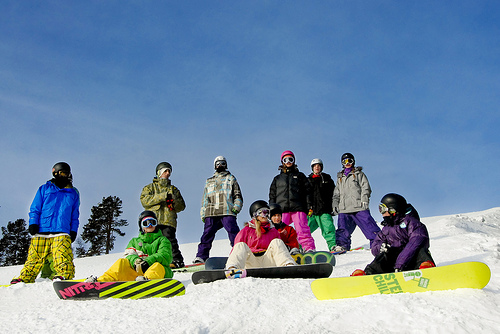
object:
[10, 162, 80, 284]
man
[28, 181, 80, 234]
blue jacket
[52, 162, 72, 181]
black mask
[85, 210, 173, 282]
man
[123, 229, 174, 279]
green jacket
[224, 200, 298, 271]
girl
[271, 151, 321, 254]
woman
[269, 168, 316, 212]
black jacket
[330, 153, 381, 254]
female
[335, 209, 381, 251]
purple pants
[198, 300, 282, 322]
snow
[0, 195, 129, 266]
trees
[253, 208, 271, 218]
goggled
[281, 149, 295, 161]
helmet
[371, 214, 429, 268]
jacket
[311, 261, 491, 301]
snowboard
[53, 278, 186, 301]
snowboard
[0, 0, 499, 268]
sky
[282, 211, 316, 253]
pants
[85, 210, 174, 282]
person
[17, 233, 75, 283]
yellow pants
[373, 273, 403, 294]
design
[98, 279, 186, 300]
stripes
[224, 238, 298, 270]
snow pants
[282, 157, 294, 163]
blue goggles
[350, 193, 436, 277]
gal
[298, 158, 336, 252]
dude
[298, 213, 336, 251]
green snow pants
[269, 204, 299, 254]
person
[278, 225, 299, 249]
red coat